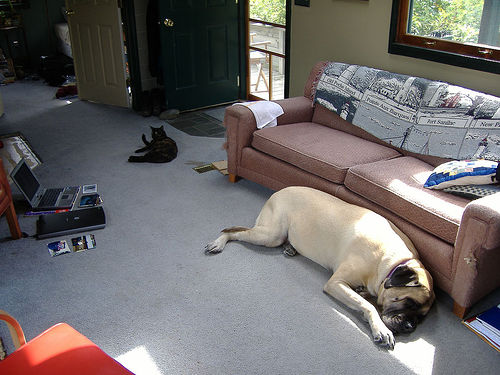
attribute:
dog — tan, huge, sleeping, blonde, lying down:
[205, 186, 435, 351]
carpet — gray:
[0, 78, 498, 374]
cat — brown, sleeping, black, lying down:
[128, 125, 178, 161]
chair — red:
[1, 313, 135, 374]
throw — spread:
[311, 60, 499, 162]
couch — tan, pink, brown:
[222, 60, 499, 318]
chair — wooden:
[248, 33, 273, 94]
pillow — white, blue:
[423, 160, 499, 191]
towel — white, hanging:
[233, 101, 285, 130]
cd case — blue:
[79, 193, 98, 208]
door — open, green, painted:
[156, 0, 240, 113]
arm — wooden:
[1, 311, 23, 348]